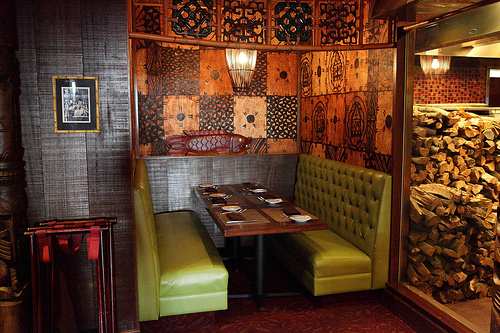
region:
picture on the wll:
[52, 73, 104, 135]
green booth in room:
[135, 145, 224, 326]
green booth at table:
[293, 151, 391, 298]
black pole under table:
[253, 235, 272, 304]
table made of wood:
[198, 182, 321, 238]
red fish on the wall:
[169, 128, 255, 159]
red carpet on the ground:
[221, 299, 410, 331]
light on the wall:
[218, 44, 260, 74]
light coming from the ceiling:
[423, 54, 459, 78]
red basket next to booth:
[32, 221, 126, 331]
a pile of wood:
[412, 102, 499, 282]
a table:
[196, 164, 314, 244]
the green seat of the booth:
[285, 157, 392, 267]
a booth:
[133, 142, 365, 284]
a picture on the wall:
[53, 75, 100, 130]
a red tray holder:
[21, 210, 125, 314]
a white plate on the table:
[222, 204, 239, 215]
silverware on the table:
[253, 193, 261, 205]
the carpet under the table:
[256, 293, 389, 332]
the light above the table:
[228, 47, 259, 98]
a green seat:
[335, 225, 373, 261]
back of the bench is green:
[322, 181, 369, 227]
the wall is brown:
[41, 132, 110, 200]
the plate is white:
[216, 202, 241, 214]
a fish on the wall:
[173, 124, 250, 156]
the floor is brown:
[283, 309, 328, 328]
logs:
[426, 124, 495, 240]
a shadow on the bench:
[307, 242, 333, 261]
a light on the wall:
[221, 52, 265, 86]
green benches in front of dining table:
[134, 139, 392, 326]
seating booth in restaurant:
[129, 119, 394, 327]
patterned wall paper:
[133, 38, 393, 170]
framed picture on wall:
[46, 69, 106, 139]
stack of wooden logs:
[402, 95, 499, 311]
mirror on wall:
[390, 0, 497, 331]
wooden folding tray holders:
[18, 209, 126, 330]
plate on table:
[216, 200, 241, 213]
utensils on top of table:
[224, 214, 259, 228]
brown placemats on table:
[211, 201, 270, 231]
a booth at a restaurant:
[116, 19, 408, 326]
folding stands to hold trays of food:
[20, 209, 125, 331]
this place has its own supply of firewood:
[398, 78, 498, 308]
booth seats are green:
[266, 146, 390, 300]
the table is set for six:
[192, 175, 321, 239]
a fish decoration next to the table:
[160, 122, 257, 160]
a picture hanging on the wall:
[46, 66, 106, 141]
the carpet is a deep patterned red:
[143, 248, 422, 331]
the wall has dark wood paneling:
[21, 5, 138, 325]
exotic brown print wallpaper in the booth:
[133, 5, 391, 166]